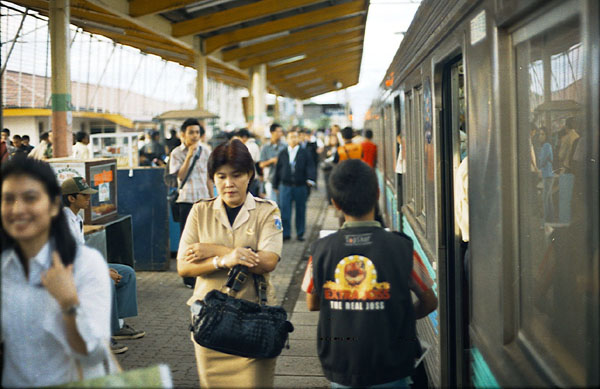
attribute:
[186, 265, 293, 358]
purse — black